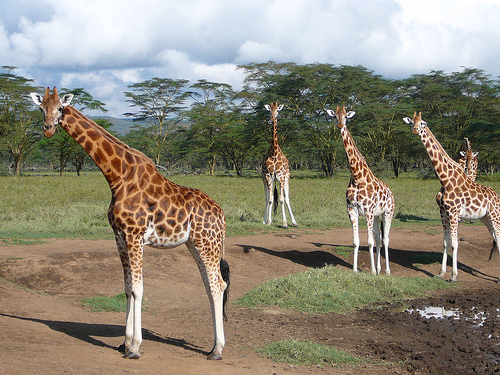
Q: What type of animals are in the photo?
A: Giraffes.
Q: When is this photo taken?
A: Daytime.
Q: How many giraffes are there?
A: Five.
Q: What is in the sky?
A: Clouds.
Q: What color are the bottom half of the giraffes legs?
A: White.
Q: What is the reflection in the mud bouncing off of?
A: Water.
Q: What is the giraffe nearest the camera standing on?
A: Dirt.